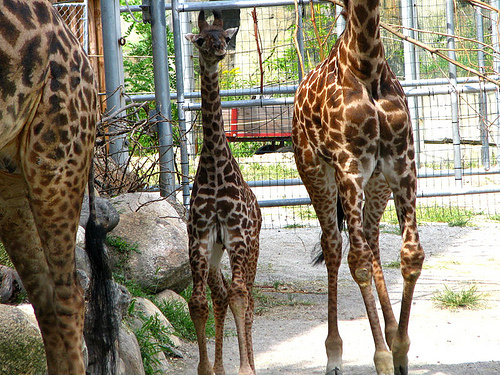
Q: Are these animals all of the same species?
A: Yes, all the animals are giraffes.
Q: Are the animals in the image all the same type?
A: Yes, all the animals are giraffes.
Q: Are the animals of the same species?
A: Yes, all the animals are giraffes.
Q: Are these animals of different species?
A: No, all the animals are giraffes.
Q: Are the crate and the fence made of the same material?
A: No, the crate is made of wood and the fence is made of metal.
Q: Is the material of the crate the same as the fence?
A: No, the crate is made of wood and the fence is made of metal.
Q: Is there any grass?
A: Yes, there is grass.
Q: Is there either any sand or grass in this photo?
A: Yes, there is grass.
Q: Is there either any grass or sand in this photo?
A: Yes, there is grass.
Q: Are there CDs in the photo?
A: No, there are no cds.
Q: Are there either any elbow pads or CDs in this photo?
A: No, there are no CDs or elbow pads.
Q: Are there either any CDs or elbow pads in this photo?
A: No, there are no CDs or elbow pads.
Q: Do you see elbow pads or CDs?
A: No, there are no CDs or elbow pads.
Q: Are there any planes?
A: No, there are no planes.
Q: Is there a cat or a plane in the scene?
A: No, there are no airplanes or cats.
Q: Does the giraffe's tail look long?
A: Yes, the tail is long.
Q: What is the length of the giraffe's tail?
A: The tail is long.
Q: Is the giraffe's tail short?
A: No, the tail is long.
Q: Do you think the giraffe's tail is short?
A: No, the tail is long.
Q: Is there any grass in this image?
A: Yes, there is grass.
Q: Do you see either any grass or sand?
A: Yes, there is grass.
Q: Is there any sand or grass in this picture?
A: Yes, there is grass.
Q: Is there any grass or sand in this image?
A: Yes, there is grass.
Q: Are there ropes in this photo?
A: No, there are no ropes.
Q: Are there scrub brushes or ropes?
A: No, there are no ropes or scrub brushes.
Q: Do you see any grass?
A: Yes, there is grass.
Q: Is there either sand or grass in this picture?
A: Yes, there is grass.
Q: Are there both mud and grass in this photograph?
A: No, there is grass but no mud.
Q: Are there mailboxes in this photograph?
A: No, there are no mailboxes.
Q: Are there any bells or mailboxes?
A: No, there are no mailboxes or bells.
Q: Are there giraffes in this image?
A: Yes, there is a giraffe.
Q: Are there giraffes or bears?
A: Yes, there is a giraffe.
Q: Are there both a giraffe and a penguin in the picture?
A: No, there is a giraffe but no penguins.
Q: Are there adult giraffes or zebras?
A: Yes, there is an adult giraffe.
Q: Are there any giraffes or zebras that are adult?
A: Yes, the giraffe is adult.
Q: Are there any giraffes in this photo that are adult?
A: Yes, there is an adult giraffe.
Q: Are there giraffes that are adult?
A: Yes, there is a giraffe that is adult.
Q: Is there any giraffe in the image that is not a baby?
A: Yes, there is a adult giraffe.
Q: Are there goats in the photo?
A: No, there are no goats.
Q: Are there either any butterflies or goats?
A: No, there are no goats or butterflies.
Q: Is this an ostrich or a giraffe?
A: This is a giraffe.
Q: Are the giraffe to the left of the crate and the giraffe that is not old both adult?
A: Yes, both the giraffe and the giraffe are adult.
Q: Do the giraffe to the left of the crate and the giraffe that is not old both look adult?
A: Yes, both the giraffe and the giraffe are adult.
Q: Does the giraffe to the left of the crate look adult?
A: Yes, the giraffe is adult.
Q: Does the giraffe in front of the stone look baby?
A: No, the giraffe is adult.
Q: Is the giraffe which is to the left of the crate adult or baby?
A: The giraffe is adult.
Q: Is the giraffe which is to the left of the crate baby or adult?
A: The giraffe is adult.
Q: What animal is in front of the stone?
A: The giraffe is in front of the stone.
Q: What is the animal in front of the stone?
A: The animal is a giraffe.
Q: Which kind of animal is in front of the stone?
A: The animal is a giraffe.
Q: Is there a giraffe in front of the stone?
A: Yes, there is a giraffe in front of the stone.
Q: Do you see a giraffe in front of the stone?
A: Yes, there is a giraffe in front of the stone.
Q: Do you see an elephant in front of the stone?
A: No, there is a giraffe in front of the stone.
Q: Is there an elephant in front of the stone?
A: No, there is a giraffe in front of the stone.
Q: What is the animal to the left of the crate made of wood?
A: The animal is a giraffe.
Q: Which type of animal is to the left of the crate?
A: The animal is a giraffe.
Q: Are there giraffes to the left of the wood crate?
A: Yes, there is a giraffe to the left of the crate.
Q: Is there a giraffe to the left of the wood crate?
A: Yes, there is a giraffe to the left of the crate.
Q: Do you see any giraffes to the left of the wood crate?
A: Yes, there is a giraffe to the left of the crate.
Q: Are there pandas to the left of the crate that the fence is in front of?
A: No, there is a giraffe to the left of the crate.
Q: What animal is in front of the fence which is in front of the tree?
A: The giraffe is in front of the fence.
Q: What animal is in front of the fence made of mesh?
A: The animal is a giraffe.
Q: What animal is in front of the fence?
A: The animal is a giraffe.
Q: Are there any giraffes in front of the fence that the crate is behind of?
A: Yes, there is a giraffe in front of the fence.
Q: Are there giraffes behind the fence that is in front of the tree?
A: No, the giraffe is in front of the fence.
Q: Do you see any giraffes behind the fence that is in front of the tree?
A: No, the giraffe is in front of the fence.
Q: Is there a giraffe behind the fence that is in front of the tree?
A: No, the giraffe is in front of the fence.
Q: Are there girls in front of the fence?
A: No, there is a giraffe in front of the fence.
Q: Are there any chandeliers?
A: No, there are no chandeliers.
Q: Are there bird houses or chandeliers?
A: No, there are no chandeliers or bird houses.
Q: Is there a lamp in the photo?
A: No, there are no lamps.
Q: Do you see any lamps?
A: No, there are no lamps.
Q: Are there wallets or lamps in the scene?
A: No, there are no lamps or wallets.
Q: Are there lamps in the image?
A: No, there are no lamps.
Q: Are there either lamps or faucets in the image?
A: No, there are no lamps or faucets.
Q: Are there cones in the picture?
A: No, there are no cones.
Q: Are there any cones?
A: No, there are no cones.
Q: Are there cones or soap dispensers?
A: No, there are no cones or soap dispensers.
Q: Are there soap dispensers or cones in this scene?
A: No, there are no cones or soap dispensers.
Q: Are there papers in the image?
A: No, there are no papers.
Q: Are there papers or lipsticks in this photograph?
A: No, there are no papers or lipsticks.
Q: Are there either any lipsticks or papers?
A: No, there are no papers or lipsticks.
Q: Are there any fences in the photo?
A: Yes, there is a fence.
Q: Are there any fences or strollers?
A: Yes, there is a fence.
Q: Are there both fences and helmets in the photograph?
A: No, there is a fence but no helmets.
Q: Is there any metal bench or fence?
A: Yes, there is a metal fence.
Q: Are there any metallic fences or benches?
A: Yes, there is a metal fence.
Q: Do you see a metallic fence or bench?
A: Yes, there is a metal fence.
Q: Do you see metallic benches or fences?
A: Yes, there is a metal fence.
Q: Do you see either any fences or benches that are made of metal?
A: Yes, the fence is made of metal.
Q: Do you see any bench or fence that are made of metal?
A: Yes, the fence is made of metal.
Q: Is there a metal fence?
A: Yes, there is a fence that is made of metal.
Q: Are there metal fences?
A: Yes, there is a fence that is made of metal.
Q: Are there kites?
A: No, there are no kites.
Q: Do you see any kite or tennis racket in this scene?
A: No, there are no kites or rackets.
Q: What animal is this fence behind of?
A: The fence is behind the giraffe.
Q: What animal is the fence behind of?
A: The fence is behind the giraffe.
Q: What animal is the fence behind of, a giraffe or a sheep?
A: The fence is behind a giraffe.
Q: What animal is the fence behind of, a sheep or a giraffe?
A: The fence is behind a giraffe.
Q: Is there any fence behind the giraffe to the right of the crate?
A: Yes, there is a fence behind the giraffe.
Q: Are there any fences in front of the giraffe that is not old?
A: No, the fence is behind the giraffe.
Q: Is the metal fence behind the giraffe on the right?
A: Yes, the fence is behind the giraffe.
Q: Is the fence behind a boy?
A: No, the fence is behind the giraffe.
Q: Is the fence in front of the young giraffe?
A: No, the fence is behind the giraffe.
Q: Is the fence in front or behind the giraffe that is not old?
A: The fence is behind the giraffe.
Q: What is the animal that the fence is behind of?
A: The animal is a giraffe.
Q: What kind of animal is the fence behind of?
A: The fence is behind the giraffe.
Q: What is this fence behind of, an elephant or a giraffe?
A: The fence is behind a giraffe.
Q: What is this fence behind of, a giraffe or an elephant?
A: The fence is behind a giraffe.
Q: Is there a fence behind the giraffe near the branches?
A: Yes, there is a fence behind the giraffe.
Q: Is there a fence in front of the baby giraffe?
A: No, the fence is behind the giraffe.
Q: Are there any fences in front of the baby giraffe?
A: No, the fence is behind the giraffe.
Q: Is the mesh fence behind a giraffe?
A: Yes, the fence is behind a giraffe.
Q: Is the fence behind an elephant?
A: No, the fence is behind a giraffe.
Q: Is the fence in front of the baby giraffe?
A: No, the fence is behind the giraffe.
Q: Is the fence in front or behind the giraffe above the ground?
A: The fence is behind the giraffe.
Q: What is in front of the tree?
A: The fence is in front of the tree.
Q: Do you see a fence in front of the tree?
A: Yes, there is a fence in front of the tree.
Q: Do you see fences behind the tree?
A: No, the fence is in front of the tree.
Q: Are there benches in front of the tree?
A: No, there is a fence in front of the tree.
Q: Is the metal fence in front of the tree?
A: Yes, the fence is in front of the tree.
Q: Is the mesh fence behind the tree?
A: No, the fence is in front of the tree.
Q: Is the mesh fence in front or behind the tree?
A: The fence is in front of the tree.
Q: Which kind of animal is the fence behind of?
A: The fence is behind the giraffe.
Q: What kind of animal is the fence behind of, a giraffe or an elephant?
A: The fence is behind a giraffe.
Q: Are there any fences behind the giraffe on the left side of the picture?
A: Yes, there is a fence behind the giraffe.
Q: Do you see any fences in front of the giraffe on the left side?
A: No, the fence is behind the giraffe.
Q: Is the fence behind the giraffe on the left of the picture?
A: Yes, the fence is behind the giraffe.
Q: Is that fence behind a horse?
A: No, the fence is behind the giraffe.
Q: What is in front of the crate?
A: The fence is in front of the crate.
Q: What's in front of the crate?
A: The fence is in front of the crate.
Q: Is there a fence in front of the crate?
A: Yes, there is a fence in front of the crate.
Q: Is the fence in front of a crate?
A: Yes, the fence is in front of a crate.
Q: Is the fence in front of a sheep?
A: No, the fence is in front of a crate.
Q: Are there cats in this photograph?
A: No, there are no cats.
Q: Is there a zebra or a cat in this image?
A: No, there are no cats or zebras.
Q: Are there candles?
A: No, there are no candles.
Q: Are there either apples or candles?
A: No, there are no candles or apples.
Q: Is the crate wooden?
A: Yes, the crate is wooden.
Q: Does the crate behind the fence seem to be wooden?
A: Yes, the crate is wooden.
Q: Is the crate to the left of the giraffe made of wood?
A: Yes, the crate is made of wood.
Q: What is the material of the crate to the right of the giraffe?
A: The crate is made of wood.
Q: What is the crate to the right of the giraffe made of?
A: The crate is made of wood.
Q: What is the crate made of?
A: The crate is made of wood.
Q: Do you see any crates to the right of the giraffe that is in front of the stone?
A: Yes, there is a crate to the right of the giraffe.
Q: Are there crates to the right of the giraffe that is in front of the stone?
A: Yes, there is a crate to the right of the giraffe.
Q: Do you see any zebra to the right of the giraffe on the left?
A: No, there is a crate to the right of the giraffe.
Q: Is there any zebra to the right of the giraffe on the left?
A: No, there is a crate to the right of the giraffe.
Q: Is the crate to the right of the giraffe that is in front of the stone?
A: Yes, the crate is to the right of the giraffe.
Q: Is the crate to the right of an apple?
A: No, the crate is to the right of the giraffe.